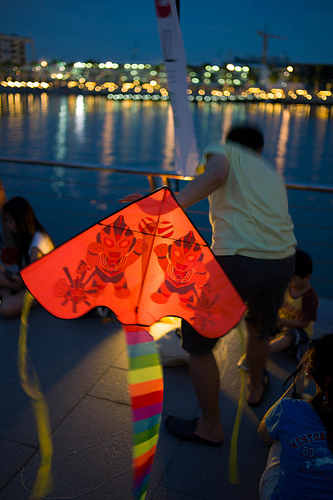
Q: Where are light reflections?
A: On the water.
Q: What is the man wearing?
A: A yellow shirt.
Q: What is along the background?
A: Lights on the shore.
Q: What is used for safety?
A: A steel balcony.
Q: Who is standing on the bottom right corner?
A: A little girl with a blue t-shirt.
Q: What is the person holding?
A: A kite.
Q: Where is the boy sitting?
A: On the ground.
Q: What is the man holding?
A: A kite.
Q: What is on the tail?
A: Rainbow.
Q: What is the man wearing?
A: White shirt.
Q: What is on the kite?
A: Warriors.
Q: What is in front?
A: Water.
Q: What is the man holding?
A: A kite.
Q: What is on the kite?
A: Two men.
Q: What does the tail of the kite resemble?
A: A rainbow.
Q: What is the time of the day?
A: This is at night.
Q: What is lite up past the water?
A: Buildings.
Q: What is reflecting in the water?
A: The building lights.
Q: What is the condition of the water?
A: Calm.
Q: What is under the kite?
A: A light.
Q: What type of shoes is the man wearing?
A: Slippers.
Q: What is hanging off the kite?
A: A tail.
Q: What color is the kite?
A: Orange, blue, yellow and cream.